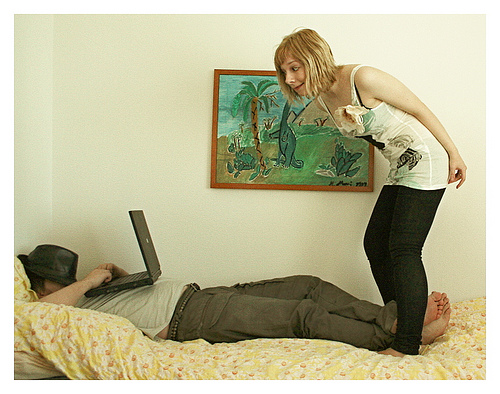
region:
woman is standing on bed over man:
[27, 28, 474, 373]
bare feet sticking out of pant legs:
[376, 260, 456, 383]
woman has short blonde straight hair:
[255, 30, 347, 117]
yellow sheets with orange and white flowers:
[211, 322, 296, 383]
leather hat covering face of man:
[18, 232, 87, 298]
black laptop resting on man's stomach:
[79, 199, 186, 299]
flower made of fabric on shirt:
[329, 100, 371, 141]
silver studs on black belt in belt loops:
[163, 291, 198, 344]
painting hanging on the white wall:
[204, 59, 384, 207]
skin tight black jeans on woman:
[358, 152, 443, 364]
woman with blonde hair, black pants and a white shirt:
[275, 26, 468, 354]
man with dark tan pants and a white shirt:
[17, 206, 449, 351]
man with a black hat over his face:
[19, 204, 453, 352]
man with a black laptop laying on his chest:
[17, 202, 452, 349]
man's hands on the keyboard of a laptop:
[89, 260, 126, 291]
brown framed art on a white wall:
[209, 67, 377, 199]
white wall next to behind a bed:
[49, 0, 480, 290]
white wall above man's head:
[13, 15, 57, 255]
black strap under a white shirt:
[352, 76, 373, 111]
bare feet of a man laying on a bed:
[421, 290, 453, 343]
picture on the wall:
[212, 68, 281, 186]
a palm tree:
[235, 80, 280, 180]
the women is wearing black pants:
[393, 198, 418, 283]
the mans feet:
[430, 298, 455, 333]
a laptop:
[117, 209, 159, 281]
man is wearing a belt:
[179, 290, 196, 301]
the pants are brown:
[227, 300, 318, 330]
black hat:
[35, 246, 70, 271]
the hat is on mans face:
[25, 248, 75, 279]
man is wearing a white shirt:
[116, 298, 170, 315]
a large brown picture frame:
[207, 65, 378, 196]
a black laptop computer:
[84, 208, 161, 296]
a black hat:
[11, 238, 82, 281]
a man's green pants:
[165, 275, 398, 352]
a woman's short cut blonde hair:
[273, 24, 340, 102]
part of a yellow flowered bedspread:
[15, 257, 495, 392]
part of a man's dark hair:
[27, 275, 44, 290]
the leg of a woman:
[388, 179, 446, 355]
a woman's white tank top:
[317, 63, 453, 191]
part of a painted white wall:
[56, 15, 212, 134]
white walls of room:
[17, 15, 482, 295]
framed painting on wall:
[210, 68, 371, 190]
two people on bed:
[21, 23, 468, 353]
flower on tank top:
[335, 101, 368, 136]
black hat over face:
[20, 242, 80, 289]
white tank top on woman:
[317, 64, 452, 191]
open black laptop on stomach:
[89, 209, 174, 319]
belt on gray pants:
[170, 284, 197, 343]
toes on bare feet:
[425, 291, 452, 341]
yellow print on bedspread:
[24, 299, 487, 380]